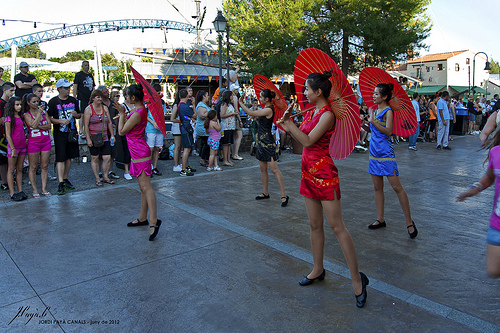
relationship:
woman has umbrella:
[279, 70, 373, 312] [129, 61, 168, 140]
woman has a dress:
[279, 70, 373, 312] [300, 102, 343, 201]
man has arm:
[46, 76, 83, 197] [46, 102, 65, 124]